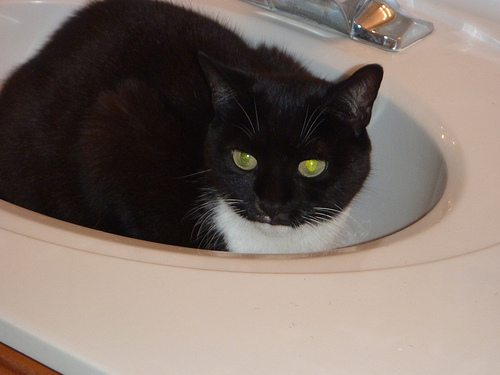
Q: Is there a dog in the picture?
A: No, there are no dogs.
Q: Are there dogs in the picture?
A: No, there are no dogs.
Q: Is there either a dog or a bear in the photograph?
A: No, there are no dogs or bears.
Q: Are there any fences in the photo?
A: No, there are no fences.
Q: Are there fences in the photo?
A: No, there are no fences.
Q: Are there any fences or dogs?
A: No, there are no fences or dogs.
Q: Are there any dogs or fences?
A: No, there are no fences or dogs.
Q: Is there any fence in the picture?
A: No, there are no fences.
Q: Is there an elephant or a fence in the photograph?
A: No, there are no fences or elephants.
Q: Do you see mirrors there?
A: No, there are no mirrors.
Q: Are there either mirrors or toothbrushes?
A: No, there are no mirrors or toothbrushes.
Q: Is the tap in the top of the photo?
A: Yes, the tap is in the top of the image.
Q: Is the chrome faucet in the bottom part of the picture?
A: No, the faucet is in the top of the image.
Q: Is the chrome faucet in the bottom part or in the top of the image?
A: The tap is in the top of the image.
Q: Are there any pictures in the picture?
A: No, there are no pictures.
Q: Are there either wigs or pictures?
A: No, there are no pictures or wigs.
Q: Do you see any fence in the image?
A: No, there are no fences.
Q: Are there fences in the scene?
A: No, there are no fences.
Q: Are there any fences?
A: No, there are no fences.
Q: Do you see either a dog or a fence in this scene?
A: No, there are no fences or dogs.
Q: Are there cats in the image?
A: Yes, there is a cat.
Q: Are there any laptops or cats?
A: Yes, there is a cat.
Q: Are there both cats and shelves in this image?
A: No, there is a cat but no shelves.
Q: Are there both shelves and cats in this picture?
A: No, there is a cat but no shelves.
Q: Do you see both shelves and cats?
A: No, there is a cat but no shelves.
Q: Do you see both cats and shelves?
A: No, there is a cat but no shelves.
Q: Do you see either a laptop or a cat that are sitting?
A: Yes, the cat is sitting.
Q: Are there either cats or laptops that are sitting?
A: Yes, the cat is sitting.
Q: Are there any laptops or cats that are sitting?
A: Yes, the cat is sitting.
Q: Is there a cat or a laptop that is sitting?
A: Yes, the cat is sitting.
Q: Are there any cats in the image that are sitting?
A: Yes, there is a cat that is sitting.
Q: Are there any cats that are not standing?
A: Yes, there is a cat that is sitting.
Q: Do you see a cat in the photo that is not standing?
A: Yes, there is a cat that is sitting .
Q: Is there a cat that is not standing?
A: Yes, there is a cat that is sitting.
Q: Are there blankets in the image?
A: No, there are no blankets.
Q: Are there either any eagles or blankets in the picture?
A: No, there are no blankets or eagles.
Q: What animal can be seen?
A: The animal is a cat.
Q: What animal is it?
A: The animal is a cat.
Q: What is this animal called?
A: That is a cat.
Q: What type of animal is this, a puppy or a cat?
A: That is a cat.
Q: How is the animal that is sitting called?
A: The animal is a cat.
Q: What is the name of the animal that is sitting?
A: The animal is a cat.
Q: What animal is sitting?
A: The animal is a cat.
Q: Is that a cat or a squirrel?
A: That is a cat.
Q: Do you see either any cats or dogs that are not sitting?
A: No, there is a cat but it is sitting.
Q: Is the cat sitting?
A: Yes, the cat is sitting.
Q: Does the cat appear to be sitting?
A: Yes, the cat is sitting.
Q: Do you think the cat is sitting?
A: Yes, the cat is sitting.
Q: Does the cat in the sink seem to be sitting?
A: Yes, the cat is sitting.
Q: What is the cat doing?
A: The cat is sitting.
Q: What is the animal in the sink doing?
A: The cat is sitting.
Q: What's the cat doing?
A: The cat is sitting.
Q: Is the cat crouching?
A: No, the cat is sitting.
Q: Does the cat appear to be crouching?
A: No, the cat is sitting.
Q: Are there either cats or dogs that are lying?
A: No, there is a cat but it is sitting.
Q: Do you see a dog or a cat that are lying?
A: No, there is a cat but it is sitting.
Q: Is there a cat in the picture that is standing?
A: No, there is a cat but it is sitting.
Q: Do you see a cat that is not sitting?
A: No, there is a cat but it is sitting.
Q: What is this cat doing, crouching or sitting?
A: The cat is sitting.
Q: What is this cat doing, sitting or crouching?
A: The cat is sitting.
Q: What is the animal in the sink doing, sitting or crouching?
A: The cat is sitting.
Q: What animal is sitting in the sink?
A: The cat is sitting in the sink.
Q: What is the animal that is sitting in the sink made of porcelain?
A: The animal is a cat.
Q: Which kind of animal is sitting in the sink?
A: The animal is a cat.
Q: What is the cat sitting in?
A: The cat is sitting in the sink.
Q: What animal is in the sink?
A: The animal is a cat.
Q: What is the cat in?
A: The cat is in the sink.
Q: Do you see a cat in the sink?
A: Yes, there is a cat in the sink.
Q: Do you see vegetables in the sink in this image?
A: No, there is a cat in the sink.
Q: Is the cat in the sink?
A: Yes, the cat is in the sink.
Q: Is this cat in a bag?
A: No, the cat is in the sink.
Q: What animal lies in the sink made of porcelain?
A: The cat lies in the sink.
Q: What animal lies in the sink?
A: The cat lies in the sink.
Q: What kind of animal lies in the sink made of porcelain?
A: The animal is a cat.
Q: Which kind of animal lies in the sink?
A: The animal is a cat.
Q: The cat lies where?
A: The cat lies in the sink.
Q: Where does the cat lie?
A: The cat lies in the sink.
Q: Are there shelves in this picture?
A: No, there are no shelves.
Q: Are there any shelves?
A: No, there are no shelves.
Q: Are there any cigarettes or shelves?
A: No, there are no shelves or cigarettes.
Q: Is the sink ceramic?
A: Yes, the sink is ceramic.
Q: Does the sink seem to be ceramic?
A: Yes, the sink is ceramic.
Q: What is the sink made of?
A: The sink is made of porcelain.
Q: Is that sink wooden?
A: No, the sink is ceramic.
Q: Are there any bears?
A: No, there are no bears.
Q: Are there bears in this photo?
A: No, there are no bears.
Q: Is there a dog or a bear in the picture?
A: No, there are no bears or dogs.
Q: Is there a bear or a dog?
A: No, there are no bears or dogs.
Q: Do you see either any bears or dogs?
A: No, there are no bears or dogs.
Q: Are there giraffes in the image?
A: No, there are no giraffes.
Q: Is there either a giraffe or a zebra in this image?
A: No, there are no giraffes or zebras.